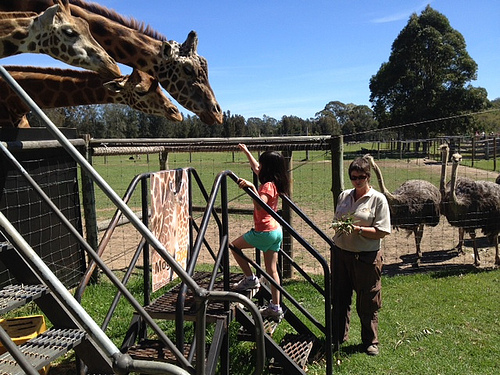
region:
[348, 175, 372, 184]
sunglasses on woman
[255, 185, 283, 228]
orange shirt on girl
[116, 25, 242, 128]
giraffes looking at the girl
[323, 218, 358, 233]
leaves in woman's hand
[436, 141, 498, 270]
ostriches in the pen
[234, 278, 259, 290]
shoe on girl foot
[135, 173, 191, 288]
sign on gate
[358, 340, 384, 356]
shoe on woman's foot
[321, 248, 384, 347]
pant on woman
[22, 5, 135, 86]
giraffe looking at girl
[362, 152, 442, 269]
ostrich is next to ostrich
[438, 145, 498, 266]
ostrich is next to ostrich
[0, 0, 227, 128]
giraffe is next to giraffe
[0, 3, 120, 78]
giraffe is next to giraffe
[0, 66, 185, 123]
giraffe is next to giraffe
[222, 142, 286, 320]
girl wearing green shorts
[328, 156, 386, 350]
person wearing brown pants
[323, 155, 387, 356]
person wearing dark sunglasses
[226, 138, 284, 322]
girl feeding tall giraffe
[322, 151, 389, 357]
Woman wearing brown pants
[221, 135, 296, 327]
Girl standing on stairs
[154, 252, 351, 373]
Stairs under the girl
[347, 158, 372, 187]
Glasses on lady's face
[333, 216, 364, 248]
Plant in the lady's hand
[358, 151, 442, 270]
Bird behind the fence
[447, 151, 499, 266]
Bird behind the fence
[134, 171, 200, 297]
Image over the stairs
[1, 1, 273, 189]
Giraffes overlooking the stairs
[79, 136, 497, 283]
Fence behind the woman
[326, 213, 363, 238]
leaves in woman hand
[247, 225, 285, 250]
green shorts on woman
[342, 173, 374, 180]
sunglasses on woman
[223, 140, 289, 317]
woman reaching for giraffe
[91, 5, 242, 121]
giraffes looking at girl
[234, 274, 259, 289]
shoes on girl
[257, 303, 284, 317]
shoes on girl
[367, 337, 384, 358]
shoe on woman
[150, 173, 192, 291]
sign on the gate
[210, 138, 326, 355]
A girl climbing some steps.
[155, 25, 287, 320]
This girl about to feed the giraffe.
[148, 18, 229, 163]
This giraffe leaning to eat the food the girl is giving it.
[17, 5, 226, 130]
Three giraffes looking for food.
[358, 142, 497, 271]
Three ostriches looking at the girl.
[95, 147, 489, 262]
A metal wired fence.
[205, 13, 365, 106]
The weather is blue clear skies.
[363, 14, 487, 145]
A large green tree in the background.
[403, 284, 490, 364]
A green, grassy terrain.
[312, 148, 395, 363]
A woman holding greens to feed the giraffes.